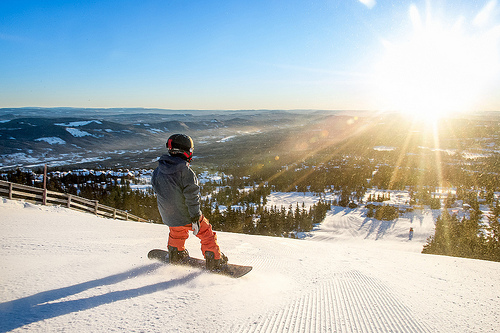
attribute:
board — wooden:
[90, 197, 100, 215]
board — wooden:
[108, 200, 129, 225]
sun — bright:
[369, 11, 485, 151]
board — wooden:
[44, 187, 65, 200]